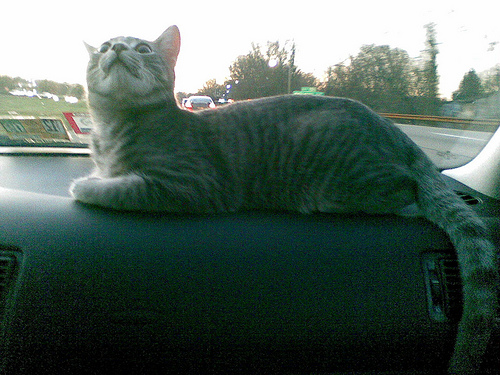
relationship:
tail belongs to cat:
[441, 172, 498, 359] [63, 16, 441, 253]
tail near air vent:
[441, 172, 498, 359] [419, 243, 466, 330]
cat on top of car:
[70, 25, 500, 375] [8, 118, 495, 373]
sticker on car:
[1, 115, 70, 145] [6, 4, 496, 373]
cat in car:
[65, 19, 490, 281] [14, 113, 458, 350]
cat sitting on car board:
[70, 25, 500, 375] [20, 183, 496, 356]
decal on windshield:
[58, 104, 92, 137] [7, 16, 499, 193]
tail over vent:
[417, 181, 496, 375] [367, 205, 492, 340]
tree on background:
[227, 49, 307, 95] [4, 0, 499, 112]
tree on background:
[175, 37, 323, 107] [4, 0, 499, 112]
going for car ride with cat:
[20, 112, 497, 311] [70, 25, 500, 375]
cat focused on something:
[70, 25, 500, 375] [67, 50, 227, 73]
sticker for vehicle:
[0, 117, 72, 142] [184, 92, 221, 106]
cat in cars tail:
[70, 25, 500, 375] [417, 191, 499, 373]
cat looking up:
[70, 25, 500, 375] [74, 49, 189, 52]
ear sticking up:
[147, 30, 198, 71] [161, 49, 177, 76]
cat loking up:
[70, 25, 500, 375] [68, 49, 167, 93]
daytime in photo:
[65, 4, 497, 126] [23, 1, 492, 367]